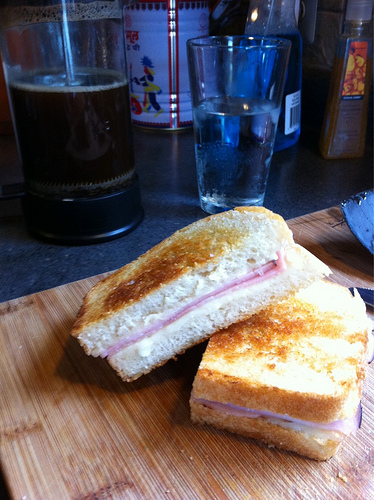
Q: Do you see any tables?
A: Yes, there is a table.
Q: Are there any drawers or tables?
A: Yes, there is a table.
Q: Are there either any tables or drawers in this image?
A: Yes, there is a table.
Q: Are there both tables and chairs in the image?
A: No, there is a table but no chairs.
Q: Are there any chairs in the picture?
A: No, there are no chairs.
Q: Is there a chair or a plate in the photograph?
A: No, there are no chairs or plates.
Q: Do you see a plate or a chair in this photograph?
A: No, there are no chairs or plates.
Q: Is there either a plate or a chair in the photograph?
A: No, there are no chairs or plates.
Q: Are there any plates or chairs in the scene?
A: No, there are no chairs or plates.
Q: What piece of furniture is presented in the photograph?
A: The piece of furniture is a table.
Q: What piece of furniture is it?
A: The piece of furniture is a table.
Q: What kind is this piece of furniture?
A: This is a table.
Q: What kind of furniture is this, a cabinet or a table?
A: This is a table.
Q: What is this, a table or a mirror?
A: This is a table.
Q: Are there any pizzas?
A: No, there are no pizzas.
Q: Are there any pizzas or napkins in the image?
A: No, there are no pizzas or napkins.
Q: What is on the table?
A: The glass is on the table.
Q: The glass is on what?
A: The glass is on the table.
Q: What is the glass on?
A: The glass is on the table.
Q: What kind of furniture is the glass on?
A: The glass is on the table.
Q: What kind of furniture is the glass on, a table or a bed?
A: The glass is on a table.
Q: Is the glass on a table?
A: Yes, the glass is on a table.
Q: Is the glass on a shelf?
A: No, the glass is on a table.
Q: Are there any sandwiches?
A: Yes, there is a sandwich.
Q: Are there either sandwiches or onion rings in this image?
A: Yes, there is a sandwich.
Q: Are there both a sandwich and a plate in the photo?
A: No, there is a sandwich but no plates.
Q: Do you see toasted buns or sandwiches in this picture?
A: Yes, there is a toasted sandwich.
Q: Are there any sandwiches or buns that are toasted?
A: Yes, the sandwich is toasted.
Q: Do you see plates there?
A: No, there are no plates.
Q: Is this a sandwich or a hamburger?
A: This is a sandwich.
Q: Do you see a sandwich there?
A: Yes, there is a sandwich.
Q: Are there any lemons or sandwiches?
A: Yes, there is a sandwich.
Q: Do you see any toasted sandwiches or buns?
A: Yes, there is a toasted sandwich.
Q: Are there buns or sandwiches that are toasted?
A: Yes, the sandwich is toasted.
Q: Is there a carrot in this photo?
A: No, there are no carrots.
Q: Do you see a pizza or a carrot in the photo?
A: No, there are no carrots or pizzas.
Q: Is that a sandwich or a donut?
A: That is a sandwich.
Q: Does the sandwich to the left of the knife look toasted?
A: Yes, the sandwich is toasted.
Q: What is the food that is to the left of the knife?
A: The food is a sandwich.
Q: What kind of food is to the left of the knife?
A: The food is a sandwich.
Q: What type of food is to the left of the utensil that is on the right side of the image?
A: The food is a sandwich.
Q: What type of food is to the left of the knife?
A: The food is a sandwich.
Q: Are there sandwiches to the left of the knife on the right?
A: Yes, there is a sandwich to the left of the knife.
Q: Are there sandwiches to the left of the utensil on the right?
A: Yes, there is a sandwich to the left of the knife.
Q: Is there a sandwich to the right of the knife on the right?
A: No, the sandwich is to the left of the knife.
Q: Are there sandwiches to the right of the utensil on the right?
A: No, the sandwich is to the left of the knife.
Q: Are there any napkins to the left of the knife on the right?
A: No, there is a sandwich to the left of the knife.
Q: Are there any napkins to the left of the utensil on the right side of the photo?
A: No, there is a sandwich to the left of the knife.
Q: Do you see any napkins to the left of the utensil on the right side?
A: No, there is a sandwich to the left of the knife.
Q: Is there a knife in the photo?
A: Yes, there is a knife.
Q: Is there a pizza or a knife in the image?
A: Yes, there is a knife.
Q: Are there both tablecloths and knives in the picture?
A: No, there is a knife but no tablecloths.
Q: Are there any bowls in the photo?
A: No, there are no bowls.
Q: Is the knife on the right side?
A: Yes, the knife is on the right of the image.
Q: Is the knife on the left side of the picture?
A: No, the knife is on the right of the image.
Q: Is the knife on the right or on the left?
A: The knife is on the right of the image.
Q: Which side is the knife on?
A: The knife is on the right of the image.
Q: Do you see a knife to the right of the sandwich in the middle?
A: Yes, there is a knife to the right of the sandwich.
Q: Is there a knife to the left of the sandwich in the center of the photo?
A: No, the knife is to the right of the sandwich.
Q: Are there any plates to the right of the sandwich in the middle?
A: No, there is a knife to the right of the sandwich.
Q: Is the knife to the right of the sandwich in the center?
A: Yes, the knife is to the right of the sandwich.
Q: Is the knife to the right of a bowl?
A: No, the knife is to the right of the sandwich.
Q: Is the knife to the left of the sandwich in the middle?
A: No, the knife is to the right of the sandwich.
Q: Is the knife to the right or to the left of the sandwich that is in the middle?
A: The knife is to the right of the sandwich.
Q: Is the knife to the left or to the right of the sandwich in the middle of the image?
A: The knife is to the right of the sandwich.